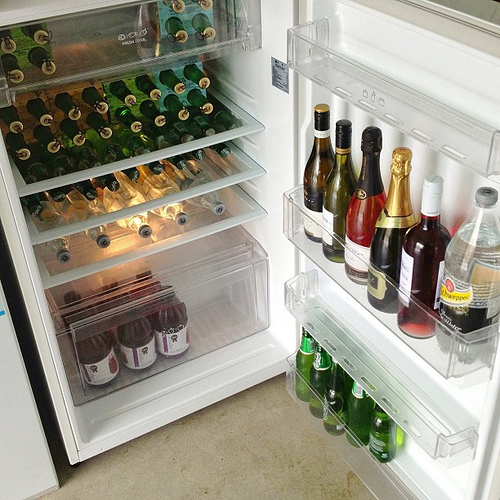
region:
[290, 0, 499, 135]
Refrigerator door shelf is empty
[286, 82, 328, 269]
Refrigerator door shelf has brown bottle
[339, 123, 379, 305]
Refrigerator has red wine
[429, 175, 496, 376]
Refrigerator has tonic water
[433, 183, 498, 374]
Tonic water is colorless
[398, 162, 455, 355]
Refrigerator has pink wine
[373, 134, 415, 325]
Wine bottle has gold foil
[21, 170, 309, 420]
Refrigerator is very clean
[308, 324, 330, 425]
Refrigerator has green bottle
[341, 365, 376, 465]
Refrigerator has green bottle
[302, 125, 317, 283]
Bottle of wine in door of fridge.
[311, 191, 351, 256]
Bottle of wine in door of fridge.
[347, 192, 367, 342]
Pink bottle of wine in door of fridge.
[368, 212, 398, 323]
Bottle of wine in door of fridge.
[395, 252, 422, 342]
Bottle of wine in door of fridge.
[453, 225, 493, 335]
Clear liquid in clear bottle.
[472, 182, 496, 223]
Gray cap on bottle.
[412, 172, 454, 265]
Bottle has white cap on top.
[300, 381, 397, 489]
Green beer bottles in door.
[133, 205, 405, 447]
Fridge door is open.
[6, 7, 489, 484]
a white refrigerator stocked with drinks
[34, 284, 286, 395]
a drawer filled with bottles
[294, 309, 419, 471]
a row of green bottles of beer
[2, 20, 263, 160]
row of wine coolers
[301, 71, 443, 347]
a selection of wines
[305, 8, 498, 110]
an empty white refrigerator shelf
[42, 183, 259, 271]
row of water bottles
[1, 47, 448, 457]
a variety of alcoholic drinks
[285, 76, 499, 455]
a fridge door full of drinks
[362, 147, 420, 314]
a wine bottle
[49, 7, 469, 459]
open refrigerator full of bottles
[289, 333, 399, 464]
green bottles in door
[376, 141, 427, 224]
gold cover on bottle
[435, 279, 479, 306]
yellow label on bottle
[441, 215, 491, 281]
clear liquid in bottle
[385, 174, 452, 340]
bottle of blush wine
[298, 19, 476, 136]
empty shelf inside of door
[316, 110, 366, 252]
bottle of white wine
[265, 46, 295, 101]
label inside of refrigerator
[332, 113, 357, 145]
black screw cap on bottle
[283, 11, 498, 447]
white interior of fridge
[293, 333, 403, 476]
green bottles in fridge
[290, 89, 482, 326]
bottles in fridge door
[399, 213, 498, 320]
clear bottle with clear liquid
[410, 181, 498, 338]
bottle with yellow label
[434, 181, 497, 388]
bottle with grey cap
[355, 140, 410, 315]
dark bottle with yellow foil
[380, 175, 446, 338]
red bottle with white label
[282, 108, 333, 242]
gold bottle with black lid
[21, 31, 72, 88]
bottles stacked next to eachother